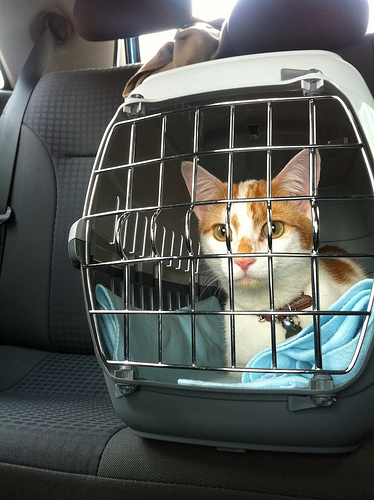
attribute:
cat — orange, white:
[178, 148, 371, 326]